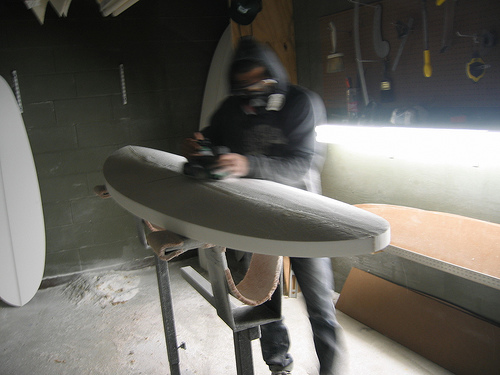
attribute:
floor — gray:
[1, 257, 448, 373]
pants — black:
[245, 178, 349, 373]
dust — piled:
[63, 266, 138, 313]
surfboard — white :
[1, 79, 46, 308]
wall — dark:
[288, 0, 489, 205]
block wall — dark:
[2, 10, 110, 278]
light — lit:
[316, 127, 456, 158]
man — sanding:
[182, 27, 361, 372]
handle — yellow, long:
[421, 47, 431, 75]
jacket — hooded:
[211, 36, 322, 193]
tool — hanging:
[334, 2, 393, 113]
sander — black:
[185, 143, 225, 181]